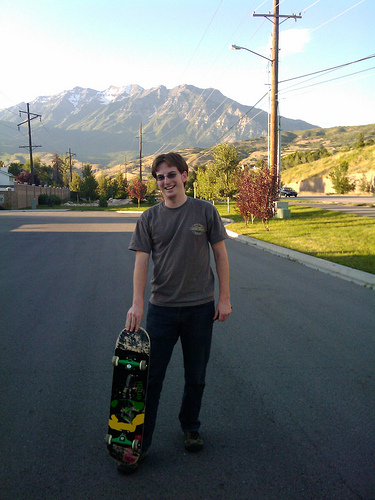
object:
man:
[118, 152, 233, 475]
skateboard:
[105, 328, 151, 468]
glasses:
[155, 171, 180, 182]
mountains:
[152, 82, 220, 158]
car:
[279, 186, 298, 199]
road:
[278, 189, 375, 215]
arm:
[124, 214, 151, 333]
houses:
[1, 161, 24, 193]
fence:
[1, 179, 70, 212]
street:
[2, 206, 374, 499]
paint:
[108, 413, 144, 434]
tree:
[255, 168, 280, 232]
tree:
[233, 167, 252, 228]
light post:
[231, 43, 281, 196]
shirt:
[128, 197, 226, 307]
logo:
[188, 222, 207, 238]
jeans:
[141, 298, 215, 448]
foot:
[115, 448, 149, 475]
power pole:
[262, 1, 291, 200]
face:
[155, 163, 187, 199]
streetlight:
[228, 43, 243, 54]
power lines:
[274, 52, 374, 83]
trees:
[78, 158, 100, 208]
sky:
[2, 1, 374, 127]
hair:
[151, 153, 188, 181]